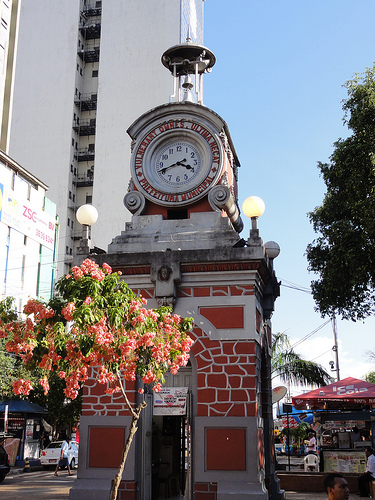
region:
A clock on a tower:
[155, 143, 203, 184]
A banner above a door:
[153, 386, 188, 413]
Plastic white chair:
[302, 453, 318, 471]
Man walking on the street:
[55, 435, 74, 475]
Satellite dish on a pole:
[271, 384, 287, 416]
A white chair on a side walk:
[301, 452, 318, 470]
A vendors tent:
[291, 377, 372, 409]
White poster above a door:
[152, 384, 187, 413]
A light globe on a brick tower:
[241, 195, 265, 217]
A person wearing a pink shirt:
[302, 431, 316, 454]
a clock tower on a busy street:
[15, 5, 356, 493]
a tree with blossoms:
[7, 256, 166, 482]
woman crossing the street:
[53, 429, 71, 474]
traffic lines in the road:
[15, 472, 75, 481]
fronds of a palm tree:
[270, 324, 324, 379]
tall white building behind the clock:
[18, 0, 199, 101]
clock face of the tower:
[132, 101, 226, 209]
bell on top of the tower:
[177, 68, 192, 87]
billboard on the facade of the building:
[0, 197, 52, 237]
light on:
[237, 187, 268, 242]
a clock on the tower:
[156, 140, 202, 182]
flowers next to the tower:
[54, 296, 165, 398]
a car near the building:
[40, 439, 58, 462]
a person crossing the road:
[57, 438, 74, 475]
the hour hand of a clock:
[174, 160, 195, 169]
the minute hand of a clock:
[158, 161, 173, 171]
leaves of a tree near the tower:
[309, 155, 373, 313]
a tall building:
[43, 0, 127, 184]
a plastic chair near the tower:
[302, 453, 317, 466]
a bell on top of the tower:
[184, 71, 193, 88]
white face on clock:
[140, 125, 220, 209]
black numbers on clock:
[166, 143, 206, 191]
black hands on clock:
[159, 143, 202, 188]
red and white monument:
[86, 119, 268, 475]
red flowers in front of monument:
[20, 252, 160, 391]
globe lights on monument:
[22, 191, 286, 263]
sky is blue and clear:
[214, 46, 293, 115]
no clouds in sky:
[241, 36, 324, 127]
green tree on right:
[271, 52, 365, 330]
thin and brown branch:
[113, 360, 137, 497]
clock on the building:
[160, 140, 198, 183]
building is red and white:
[92, 248, 280, 496]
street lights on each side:
[65, 198, 266, 242]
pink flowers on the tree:
[23, 254, 195, 490]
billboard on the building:
[9, 183, 77, 255]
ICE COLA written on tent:
[285, 364, 374, 421]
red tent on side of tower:
[281, 368, 373, 424]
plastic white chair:
[298, 449, 321, 473]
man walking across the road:
[55, 435, 81, 484]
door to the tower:
[132, 326, 205, 492]